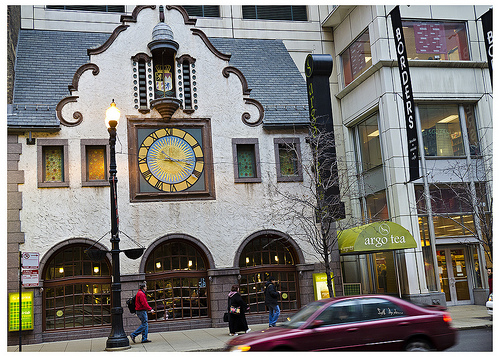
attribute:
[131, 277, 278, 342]
person — walking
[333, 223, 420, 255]
awning — green arch, white, green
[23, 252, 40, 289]
sign — white, red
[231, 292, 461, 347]
car — red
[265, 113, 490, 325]
trees — bare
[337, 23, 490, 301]
windows — large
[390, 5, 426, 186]
banner — black, large, borders, white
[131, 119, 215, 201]
clock — yellow, blue, large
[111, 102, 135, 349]
pole — old fashioned, black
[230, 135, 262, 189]
window — small, above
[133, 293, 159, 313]
jacket — red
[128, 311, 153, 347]
jeans — blue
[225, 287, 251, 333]
women — standing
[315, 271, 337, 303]
sign boards — white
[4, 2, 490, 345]
building — multistoried